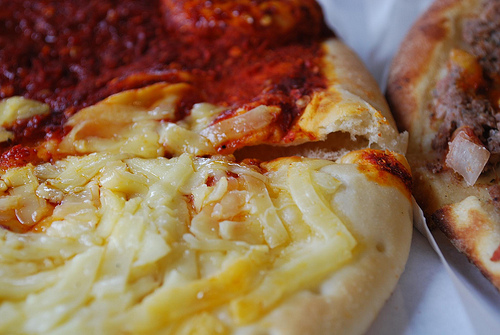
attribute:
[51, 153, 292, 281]
cheesy — melted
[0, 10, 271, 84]
sauce — red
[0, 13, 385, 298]
pizza — bigger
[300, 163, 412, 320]
crust — yellow, burnt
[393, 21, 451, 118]
bread — brown, toasted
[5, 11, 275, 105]
background — unfocused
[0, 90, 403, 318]
food — yellow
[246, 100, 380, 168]
bread — breaking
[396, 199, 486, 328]
cloth — white